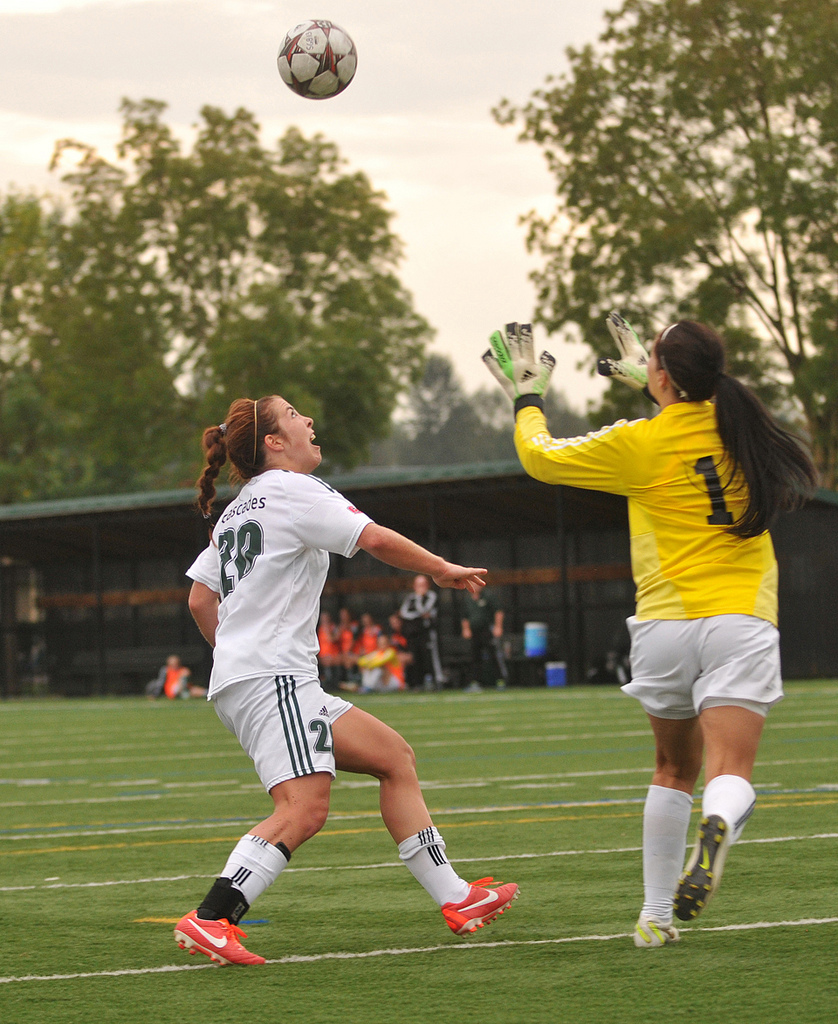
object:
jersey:
[508, 393, 780, 626]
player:
[482, 310, 822, 945]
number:
[693, 455, 736, 526]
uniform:
[178, 466, 388, 781]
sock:
[630, 785, 691, 946]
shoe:
[174, 908, 271, 965]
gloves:
[480, 322, 556, 405]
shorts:
[211, 676, 362, 788]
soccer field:
[0, 684, 838, 1015]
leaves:
[0, 95, 434, 518]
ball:
[277, 17, 359, 99]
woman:
[175, 394, 521, 965]